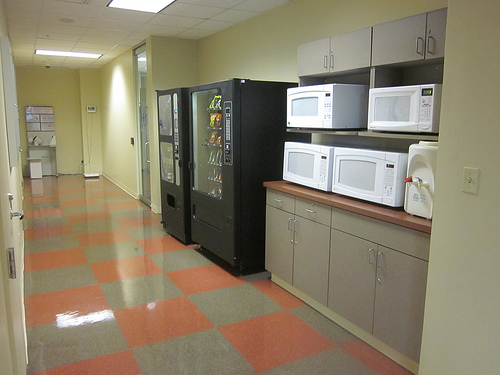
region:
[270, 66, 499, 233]
four microwaves in a break room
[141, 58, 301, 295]
two black vending machines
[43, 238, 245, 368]
grey and orange checkered floor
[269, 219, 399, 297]
grey colored cabinetry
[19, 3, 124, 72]
ceiling tiles and lighting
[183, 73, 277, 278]
snacks in a vending machine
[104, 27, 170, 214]
a glass door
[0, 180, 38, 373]
a door hinge and handle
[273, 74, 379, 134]
a white microwave oven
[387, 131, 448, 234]
a beverage dispensor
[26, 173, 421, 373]
Gray and orange floor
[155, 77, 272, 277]
Two vending machines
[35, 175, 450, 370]
Floor has a square-tile design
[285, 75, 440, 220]
4 microwaves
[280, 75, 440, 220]
Top right microwave is different than the others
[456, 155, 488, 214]
Light switch on the wall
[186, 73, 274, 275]
Vending machine dispenses candy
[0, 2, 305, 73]
Ceiling has white square tiles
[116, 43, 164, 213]
Door is clear with silver edges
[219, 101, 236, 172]
Buttons to push on the vending machine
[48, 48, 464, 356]
kitchen area for office workers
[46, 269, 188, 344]
floor is shiny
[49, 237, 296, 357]
floor is large squares of orange and grey tiles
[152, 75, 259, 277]
black vending machines for snacks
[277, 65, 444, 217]
four white microwaves are on two shelves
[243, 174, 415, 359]
cabinets are grey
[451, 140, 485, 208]
light switch on wall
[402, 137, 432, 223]
water dispenser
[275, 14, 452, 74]
small gray cabinets above the microwaves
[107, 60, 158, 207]
glass door with handle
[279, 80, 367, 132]
a white microwave on a shelf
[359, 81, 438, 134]
a white microwave on a shelf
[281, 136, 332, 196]
a white microwave on a shelf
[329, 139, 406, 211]
a white microwave on a shelf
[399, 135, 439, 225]
a white water cooler on a shelf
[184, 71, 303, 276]
a black candy machine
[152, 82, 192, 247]
a black vending machine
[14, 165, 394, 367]
orange and tan squared tile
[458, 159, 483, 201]
a light wall switch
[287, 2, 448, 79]
a row of overhead cabinets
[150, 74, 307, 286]
TWO BLACK VENDING MACHINES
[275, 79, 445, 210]
FOUR WHITE MICROWAVES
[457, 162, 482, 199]
A LIGHT SWITCH ON THE WALL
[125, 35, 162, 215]
A GLASS DOOR WITH A METAL HANDLE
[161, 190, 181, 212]
THE OPENING OF A VENDING MACHINE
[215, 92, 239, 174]
THE BUTTONS OF A VENDING MACHINE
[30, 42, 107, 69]
BRIGHT FLORESCENT LIGHTS IN THE CEILING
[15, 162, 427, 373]
ORANGE AND GRAY FLOOR TILES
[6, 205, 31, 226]
A SILVER DOOR HANDLE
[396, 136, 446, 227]
A JUG CONTAINING HOT AND COLD WATER